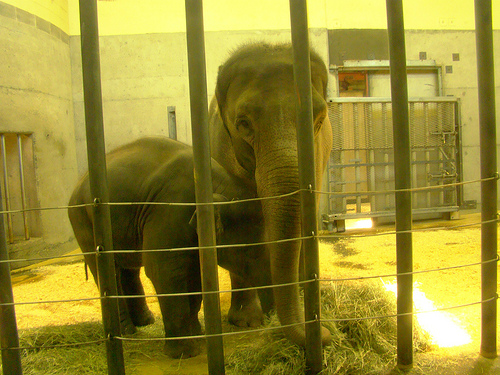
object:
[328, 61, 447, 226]
door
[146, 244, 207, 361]
leg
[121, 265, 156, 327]
leg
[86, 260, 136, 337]
leg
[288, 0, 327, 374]
bar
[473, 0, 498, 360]
bar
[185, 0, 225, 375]
bar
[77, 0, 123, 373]
bar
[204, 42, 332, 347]
elephant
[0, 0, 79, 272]
wall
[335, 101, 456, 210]
fence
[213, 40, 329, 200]
head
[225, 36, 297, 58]
hairs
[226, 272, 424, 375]
greengrass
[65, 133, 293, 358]
elephant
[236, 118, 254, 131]
eyes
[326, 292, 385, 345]
hay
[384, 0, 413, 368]
bar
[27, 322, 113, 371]
straw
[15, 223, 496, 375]
ground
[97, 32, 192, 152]
walls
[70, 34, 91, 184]
walls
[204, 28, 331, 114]
walls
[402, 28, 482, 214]
walls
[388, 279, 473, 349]
light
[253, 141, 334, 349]
trunk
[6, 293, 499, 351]
wire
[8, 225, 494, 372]
floor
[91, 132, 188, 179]
back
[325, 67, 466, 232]
cage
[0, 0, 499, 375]
cage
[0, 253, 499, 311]
wires